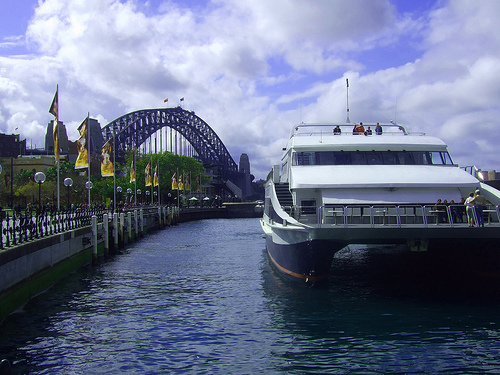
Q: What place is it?
A: It is a sea.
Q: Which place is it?
A: It is a sea.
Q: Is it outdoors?
A: Yes, it is outdoors.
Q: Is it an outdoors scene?
A: Yes, it is outdoors.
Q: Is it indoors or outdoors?
A: It is outdoors.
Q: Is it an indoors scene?
A: No, it is outdoors.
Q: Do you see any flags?
A: Yes, there is a flag.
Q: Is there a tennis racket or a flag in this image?
A: Yes, there is a flag.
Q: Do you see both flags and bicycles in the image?
A: No, there is a flag but no bicycles.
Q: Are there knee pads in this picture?
A: No, there are no knee pads.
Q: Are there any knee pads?
A: No, there are no knee pads.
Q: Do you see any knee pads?
A: No, there are no knee pads.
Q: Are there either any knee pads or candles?
A: No, there are no knee pads or candles.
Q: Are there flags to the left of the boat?
A: Yes, there is a flag to the left of the boat.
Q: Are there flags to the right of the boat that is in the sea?
A: No, the flag is to the left of the boat.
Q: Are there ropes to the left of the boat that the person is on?
A: No, there is a flag to the left of the boat.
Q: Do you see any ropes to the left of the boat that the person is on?
A: No, there is a flag to the left of the boat.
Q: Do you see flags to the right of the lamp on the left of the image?
A: Yes, there is a flag to the right of the lamp.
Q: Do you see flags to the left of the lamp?
A: No, the flag is to the right of the lamp.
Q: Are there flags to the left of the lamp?
A: No, the flag is to the right of the lamp.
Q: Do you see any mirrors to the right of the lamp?
A: No, there is a flag to the right of the lamp.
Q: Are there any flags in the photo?
A: Yes, there is a flag.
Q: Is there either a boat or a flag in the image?
A: Yes, there is a flag.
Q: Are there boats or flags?
A: Yes, there is a flag.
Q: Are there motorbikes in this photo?
A: No, there are no motorbikes.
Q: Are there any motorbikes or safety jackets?
A: No, there are no motorbikes or safety jackets.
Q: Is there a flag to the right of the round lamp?
A: Yes, there is a flag to the right of the lamp.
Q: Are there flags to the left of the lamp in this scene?
A: No, the flag is to the right of the lamp.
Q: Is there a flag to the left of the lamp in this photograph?
A: No, the flag is to the right of the lamp.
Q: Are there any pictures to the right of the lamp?
A: No, there is a flag to the right of the lamp.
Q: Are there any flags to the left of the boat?
A: Yes, there is a flag to the left of the boat.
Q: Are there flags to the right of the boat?
A: No, the flag is to the left of the boat.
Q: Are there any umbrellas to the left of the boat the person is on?
A: No, there is a flag to the left of the boat.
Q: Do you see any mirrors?
A: No, there are no mirrors.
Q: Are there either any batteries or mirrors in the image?
A: No, there are no mirrors or batteries.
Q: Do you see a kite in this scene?
A: No, there are no kites.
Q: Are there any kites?
A: No, there are no kites.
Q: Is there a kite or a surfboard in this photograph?
A: No, there are no kites or surfboards.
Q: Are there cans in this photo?
A: No, there are no cans.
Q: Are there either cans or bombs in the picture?
A: No, there are no cans or bombs.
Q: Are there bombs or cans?
A: No, there are no cans or bombs.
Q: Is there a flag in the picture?
A: Yes, there is a flag.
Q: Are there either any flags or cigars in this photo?
A: Yes, there is a flag.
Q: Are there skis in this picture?
A: No, there are no skis.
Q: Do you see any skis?
A: No, there are no skis.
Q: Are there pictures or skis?
A: No, there are no skis or pictures.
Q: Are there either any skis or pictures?
A: No, there are no skis or pictures.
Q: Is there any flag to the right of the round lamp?
A: Yes, there is a flag to the right of the lamp.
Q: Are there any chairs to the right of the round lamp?
A: No, there is a flag to the right of the lamp.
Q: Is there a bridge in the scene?
A: Yes, there is a bridge.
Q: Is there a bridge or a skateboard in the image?
A: Yes, there is a bridge.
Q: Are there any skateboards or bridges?
A: Yes, there is a bridge.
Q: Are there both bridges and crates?
A: No, there is a bridge but no crates.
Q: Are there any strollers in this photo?
A: No, there are no strollers.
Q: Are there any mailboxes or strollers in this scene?
A: No, there are no strollers or mailboxes.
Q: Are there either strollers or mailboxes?
A: No, there are no strollers or mailboxes.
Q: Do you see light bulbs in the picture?
A: No, there are no light bulbs.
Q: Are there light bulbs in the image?
A: No, there are no light bulbs.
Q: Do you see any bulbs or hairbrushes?
A: No, there are no bulbs or hairbrushes.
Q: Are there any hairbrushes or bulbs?
A: No, there are no bulbs or hairbrushes.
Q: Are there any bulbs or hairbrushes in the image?
A: No, there are no bulbs or hairbrushes.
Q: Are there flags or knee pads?
A: Yes, there is a flag.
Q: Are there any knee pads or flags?
A: Yes, there is a flag.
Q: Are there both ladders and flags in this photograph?
A: No, there is a flag but no ladders.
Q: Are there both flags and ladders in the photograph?
A: No, there is a flag but no ladders.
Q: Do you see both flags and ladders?
A: No, there is a flag but no ladders.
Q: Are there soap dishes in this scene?
A: No, there are no soap dishes.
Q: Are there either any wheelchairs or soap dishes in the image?
A: No, there are no soap dishes or wheelchairs.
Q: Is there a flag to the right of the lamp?
A: Yes, there is a flag to the right of the lamp.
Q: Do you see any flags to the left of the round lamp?
A: No, the flag is to the right of the lamp.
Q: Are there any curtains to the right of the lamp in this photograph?
A: No, there is a flag to the right of the lamp.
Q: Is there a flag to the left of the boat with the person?
A: Yes, there is a flag to the left of the boat.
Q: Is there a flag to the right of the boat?
A: No, the flag is to the left of the boat.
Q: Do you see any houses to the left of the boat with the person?
A: No, there is a flag to the left of the boat.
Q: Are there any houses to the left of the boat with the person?
A: No, there is a flag to the left of the boat.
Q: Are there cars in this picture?
A: No, there are no cars.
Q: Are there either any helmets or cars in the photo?
A: No, there are no cars or helmets.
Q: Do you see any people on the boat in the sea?
A: Yes, there is a person on the boat.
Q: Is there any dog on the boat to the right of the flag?
A: No, there is a person on the boat.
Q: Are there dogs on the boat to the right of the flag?
A: No, there is a person on the boat.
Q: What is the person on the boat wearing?
A: The person is wearing a shirt.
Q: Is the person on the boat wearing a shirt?
A: Yes, the person is wearing a shirt.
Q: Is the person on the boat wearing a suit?
A: No, the person is wearing a shirt.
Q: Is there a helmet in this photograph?
A: No, there are no helmets.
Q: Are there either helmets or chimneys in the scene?
A: No, there are no helmets or chimneys.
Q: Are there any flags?
A: Yes, there is a flag.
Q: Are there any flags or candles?
A: Yes, there is a flag.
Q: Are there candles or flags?
A: Yes, there is a flag.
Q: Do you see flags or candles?
A: Yes, there is a flag.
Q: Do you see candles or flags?
A: Yes, there is a flag.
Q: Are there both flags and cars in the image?
A: No, there is a flag but no cars.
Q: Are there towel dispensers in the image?
A: No, there are no towel dispensers.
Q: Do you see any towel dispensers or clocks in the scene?
A: No, there are no towel dispensers or clocks.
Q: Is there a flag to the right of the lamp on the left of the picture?
A: Yes, there is a flag to the right of the lamp.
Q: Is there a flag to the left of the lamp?
A: No, the flag is to the right of the lamp.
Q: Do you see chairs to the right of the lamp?
A: No, there is a flag to the right of the lamp.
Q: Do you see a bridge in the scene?
A: Yes, there is a bridge.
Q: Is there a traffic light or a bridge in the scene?
A: Yes, there is a bridge.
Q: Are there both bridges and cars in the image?
A: No, there is a bridge but no cars.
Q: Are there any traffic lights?
A: No, there are no traffic lights.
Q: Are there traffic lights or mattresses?
A: No, there are no traffic lights or mattresses.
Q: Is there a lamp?
A: Yes, there is a lamp.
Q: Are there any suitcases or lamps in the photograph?
A: Yes, there is a lamp.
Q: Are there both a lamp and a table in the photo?
A: No, there is a lamp but no tables.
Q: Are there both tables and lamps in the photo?
A: No, there is a lamp but no tables.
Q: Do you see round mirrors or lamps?
A: Yes, there is a round lamp.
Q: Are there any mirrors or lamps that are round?
A: Yes, the lamp is round.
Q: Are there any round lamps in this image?
A: Yes, there is a round lamp.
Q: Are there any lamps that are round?
A: Yes, there is a round lamp.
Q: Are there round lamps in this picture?
A: Yes, there is a round lamp.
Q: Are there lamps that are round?
A: Yes, there is a lamp that is round.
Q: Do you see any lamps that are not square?
A: Yes, there is a round lamp.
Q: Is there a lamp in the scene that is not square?
A: Yes, there is a round lamp.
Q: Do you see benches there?
A: No, there are no benches.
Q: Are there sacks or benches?
A: No, there are no benches or sacks.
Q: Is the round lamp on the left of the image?
A: Yes, the lamp is on the left of the image.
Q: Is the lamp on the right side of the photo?
A: No, the lamp is on the left of the image.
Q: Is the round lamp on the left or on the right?
A: The lamp is on the left of the image.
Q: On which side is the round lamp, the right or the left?
A: The lamp is on the left of the image.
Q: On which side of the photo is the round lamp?
A: The lamp is on the left of the image.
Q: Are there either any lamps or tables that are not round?
A: No, there is a lamp but it is round.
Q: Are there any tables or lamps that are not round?
A: No, there is a lamp but it is round.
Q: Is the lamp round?
A: Yes, the lamp is round.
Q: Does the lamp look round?
A: Yes, the lamp is round.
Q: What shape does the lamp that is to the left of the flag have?
A: The lamp has round shape.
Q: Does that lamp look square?
A: No, the lamp is round.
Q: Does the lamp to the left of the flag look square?
A: No, the lamp is round.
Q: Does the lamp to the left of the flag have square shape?
A: No, the lamp is round.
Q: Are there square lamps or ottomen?
A: No, there is a lamp but it is round.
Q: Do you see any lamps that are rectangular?
A: No, there is a lamp but it is round.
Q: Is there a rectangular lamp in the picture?
A: No, there is a lamp but it is round.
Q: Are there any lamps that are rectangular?
A: No, there is a lamp but it is round.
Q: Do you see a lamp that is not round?
A: No, there is a lamp but it is round.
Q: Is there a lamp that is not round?
A: No, there is a lamp but it is round.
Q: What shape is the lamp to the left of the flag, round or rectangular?
A: The lamp is round.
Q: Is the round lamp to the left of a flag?
A: Yes, the lamp is to the left of a flag.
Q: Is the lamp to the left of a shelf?
A: No, the lamp is to the left of a flag.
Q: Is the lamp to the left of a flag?
A: Yes, the lamp is to the left of a flag.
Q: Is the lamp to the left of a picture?
A: No, the lamp is to the left of a flag.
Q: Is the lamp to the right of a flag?
A: No, the lamp is to the left of a flag.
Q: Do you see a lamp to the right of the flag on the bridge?
A: No, the lamp is to the left of the flag.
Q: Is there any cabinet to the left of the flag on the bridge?
A: No, there is a lamp to the left of the flag.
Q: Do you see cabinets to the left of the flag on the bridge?
A: No, there is a lamp to the left of the flag.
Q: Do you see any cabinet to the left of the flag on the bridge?
A: No, there is a lamp to the left of the flag.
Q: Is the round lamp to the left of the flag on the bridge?
A: Yes, the lamp is to the left of the flag.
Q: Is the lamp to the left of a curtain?
A: No, the lamp is to the left of the flag.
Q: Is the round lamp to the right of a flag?
A: No, the lamp is to the left of a flag.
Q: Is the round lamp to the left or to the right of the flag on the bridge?
A: The lamp is to the left of the flag.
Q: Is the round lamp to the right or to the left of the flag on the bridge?
A: The lamp is to the left of the flag.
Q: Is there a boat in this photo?
A: Yes, there is a boat.